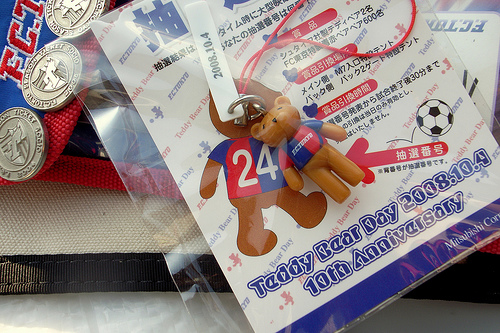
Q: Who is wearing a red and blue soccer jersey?
A: Toy bear.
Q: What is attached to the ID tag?
A: A toy bear.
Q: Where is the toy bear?
A: In a plastic bag.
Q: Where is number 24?
A: On the bear's shirt on the picture.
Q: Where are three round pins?
A: Left from the toy bear.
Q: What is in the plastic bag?
A: A toy bear and a card.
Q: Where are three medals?
A: On the flap.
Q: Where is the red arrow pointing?
A: At the bear.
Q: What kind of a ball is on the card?
A: Soccer ball.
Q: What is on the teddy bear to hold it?
A: Band.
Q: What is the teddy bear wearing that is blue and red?
A: Shirt.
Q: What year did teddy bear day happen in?
A: 2008.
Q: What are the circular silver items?
A: Coins.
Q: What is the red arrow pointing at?
A: Teddy bear.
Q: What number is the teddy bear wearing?
A: 24.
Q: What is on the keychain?
A: Teddy bear.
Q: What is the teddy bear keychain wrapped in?
A: Plastic.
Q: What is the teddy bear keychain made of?
A: Plastic.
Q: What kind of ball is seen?
A: Soccer.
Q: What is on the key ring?
A: Small plastic bear.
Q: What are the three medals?
A: Row.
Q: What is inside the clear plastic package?
A: The bear.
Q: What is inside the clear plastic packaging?
A: The information card.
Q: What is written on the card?
A: A foreign language.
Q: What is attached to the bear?
A: Red plastic string.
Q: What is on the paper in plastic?
A: Image of bear drawn behind.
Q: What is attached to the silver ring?
A: Red rope above the head of bear.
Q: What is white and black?
A: Soccer ball drawn on paper.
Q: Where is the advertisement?
A: In plastic.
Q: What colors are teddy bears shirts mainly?
A: Red and blue.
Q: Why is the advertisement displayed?
A: So people will know about it.